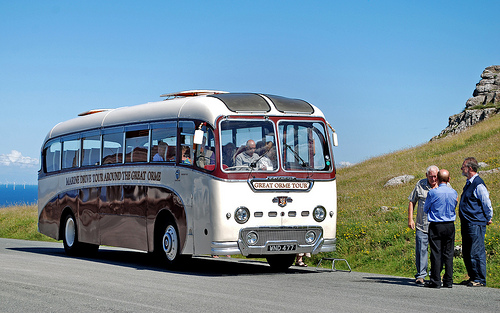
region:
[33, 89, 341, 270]
reddish-brown and off-white tour bus with people inside it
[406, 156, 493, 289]
three men standing on th eside of the road in a probable discussion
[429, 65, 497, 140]
large multi-layered rock wall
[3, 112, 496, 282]
genlte sloping hill with grass, dandylions and rocks on it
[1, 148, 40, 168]
far distant snowy mountain peak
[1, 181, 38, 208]
partial body of water with three white pole-like objects in it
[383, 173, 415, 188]
boulder surrounded by grass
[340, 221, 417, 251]
dandylions spread out through a grassy bank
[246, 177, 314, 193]
sign on a bus that reads "GREAT ORME TOUR" whtie, black and brown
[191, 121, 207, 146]
white side mirror on a bus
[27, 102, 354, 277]
this is a bus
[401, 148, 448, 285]
this is a person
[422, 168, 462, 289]
this is a person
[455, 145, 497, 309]
this is a person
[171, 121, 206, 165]
this is a window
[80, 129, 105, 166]
this is a window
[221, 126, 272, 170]
this is a window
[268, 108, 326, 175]
this is a window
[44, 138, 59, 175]
this is a window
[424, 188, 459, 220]
the shirt is blue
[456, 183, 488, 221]
the vest is blue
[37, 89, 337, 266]
the bus on the road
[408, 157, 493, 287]
the people on the road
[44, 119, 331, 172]
the windows on the bus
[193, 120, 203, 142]
the side view mirror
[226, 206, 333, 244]
the lights on the bus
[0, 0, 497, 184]
the blue sky above the bus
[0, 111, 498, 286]
the grass next to the bus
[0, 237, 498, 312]
the road under the bus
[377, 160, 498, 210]
the big rocks on the grass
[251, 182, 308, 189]
the words on the front of the bus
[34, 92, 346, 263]
a vintage white bus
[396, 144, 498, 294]
three people are talking